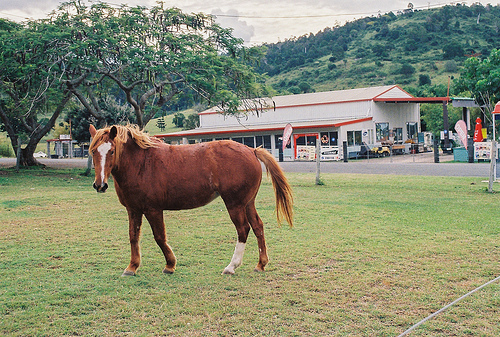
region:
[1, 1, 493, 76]
grey skies over trees and hills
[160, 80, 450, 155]
wide gray building with red border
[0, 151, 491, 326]
flat lawn of brown and green grass by road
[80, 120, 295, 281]
brown horse standing on grass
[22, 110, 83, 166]
open gray structure on other side of road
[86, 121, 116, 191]
horse with long white marking on head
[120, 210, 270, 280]
three brown legs and one partially white one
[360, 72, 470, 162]
extended overhang on side of building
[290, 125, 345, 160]
large signs below dark windows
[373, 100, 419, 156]
glass doors between large windows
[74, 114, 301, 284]
brown horse in field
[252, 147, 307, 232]
brown horse tail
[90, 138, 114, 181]
white stripe on horse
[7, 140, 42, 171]
tree trunk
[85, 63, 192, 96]
brown tree branches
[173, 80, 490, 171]
red and gray gas station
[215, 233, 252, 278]
white horse leg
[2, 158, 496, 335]
green grass field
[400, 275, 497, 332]
white line in grass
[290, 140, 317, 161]
advertisement on front of building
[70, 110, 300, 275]
a horse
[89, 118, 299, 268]
a brown horse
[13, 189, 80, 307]
a field of grass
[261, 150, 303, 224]
the tail of the horse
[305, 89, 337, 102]
the roof of the building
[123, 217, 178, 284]
front legs of the horse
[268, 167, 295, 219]
the tail is brown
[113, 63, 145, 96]
tree branches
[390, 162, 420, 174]
the street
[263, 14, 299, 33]
clouds in the sky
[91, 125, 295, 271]
a horse on the grass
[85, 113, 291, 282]
a brown and white horse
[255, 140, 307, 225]
the tail of the horse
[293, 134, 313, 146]
windows on the building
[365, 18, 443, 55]
trees on the hill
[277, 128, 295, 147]
a flag in front of the building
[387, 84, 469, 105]
a ledge on the building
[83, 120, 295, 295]
a horse standing up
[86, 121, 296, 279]
the horse is brown in color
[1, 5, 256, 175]
trees are near the horse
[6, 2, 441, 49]
the sky is very cloudy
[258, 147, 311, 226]
the tail of the horse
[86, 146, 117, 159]
the eyes of the horse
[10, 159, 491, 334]
grass covering the ground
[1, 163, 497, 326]
the grass is green and brown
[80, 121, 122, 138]
the ears of the horse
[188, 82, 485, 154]
a building around the horse